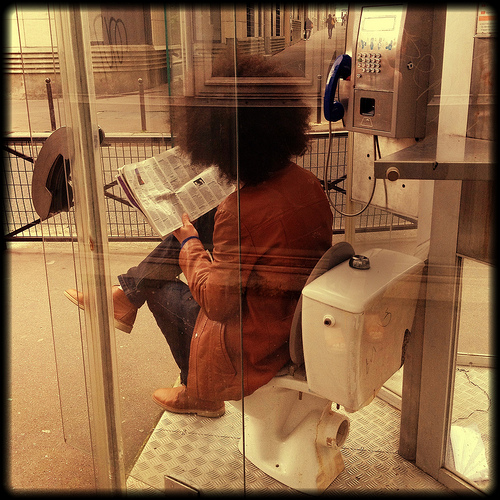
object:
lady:
[60, 50, 336, 419]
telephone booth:
[50, 11, 498, 499]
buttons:
[376, 67, 382, 73]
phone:
[321, 3, 436, 218]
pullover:
[177, 158, 334, 404]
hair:
[167, 52, 315, 188]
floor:
[122, 364, 491, 493]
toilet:
[226, 245, 428, 498]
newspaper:
[112, 146, 244, 244]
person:
[323, 13, 336, 39]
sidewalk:
[249, 20, 345, 124]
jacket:
[175, 159, 335, 403]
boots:
[62, 281, 141, 335]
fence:
[0, 129, 420, 243]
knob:
[349, 254, 371, 270]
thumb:
[182, 212, 192, 227]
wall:
[396, 6, 478, 475]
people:
[302, 17, 314, 41]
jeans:
[116, 206, 220, 390]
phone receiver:
[323, 53, 353, 123]